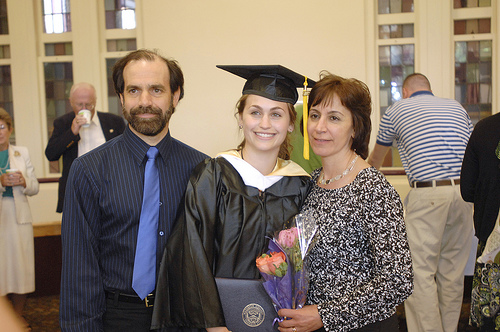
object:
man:
[57, 47, 211, 330]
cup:
[78, 109, 93, 127]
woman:
[1, 108, 41, 317]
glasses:
[0, 124, 7, 130]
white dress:
[0, 145, 40, 296]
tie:
[132, 142, 160, 301]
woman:
[149, 62, 320, 332]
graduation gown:
[150, 153, 311, 332]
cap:
[215, 65, 318, 161]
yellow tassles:
[302, 76, 312, 160]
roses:
[254, 251, 300, 315]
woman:
[256, 73, 412, 332]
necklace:
[317, 155, 362, 186]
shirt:
[376, 90, 475, 183]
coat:
[1, 144, 40, 222]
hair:
[300, 76, 372, 157]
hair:
[0, 107, 13, 132]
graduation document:
[214, 275, 281, 331]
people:
[0, 49, 499, 332]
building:
[0, 2, 500, 331]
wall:
[0, 1, 499, 228]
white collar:
[217, 149, 310, 190]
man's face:
[121, 60, 174, 135]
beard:
[120, 102, 174, 135]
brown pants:
[316, 316, 396, 331]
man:
[45, 83, 126, 215]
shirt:
[59, 126, 210, 332]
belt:
[104, 290, 161, 308]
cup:
[5, 169, 19, 185]